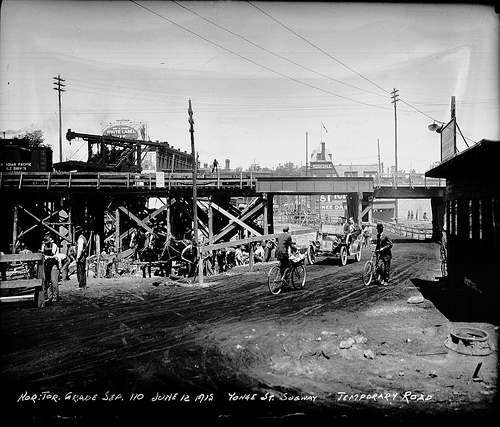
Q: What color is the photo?
A: Black and white.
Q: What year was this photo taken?
A: 1915.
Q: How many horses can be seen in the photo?
A: Two.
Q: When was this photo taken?
A: In 1915.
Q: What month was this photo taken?
A: In June.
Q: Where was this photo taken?
A: In a city.